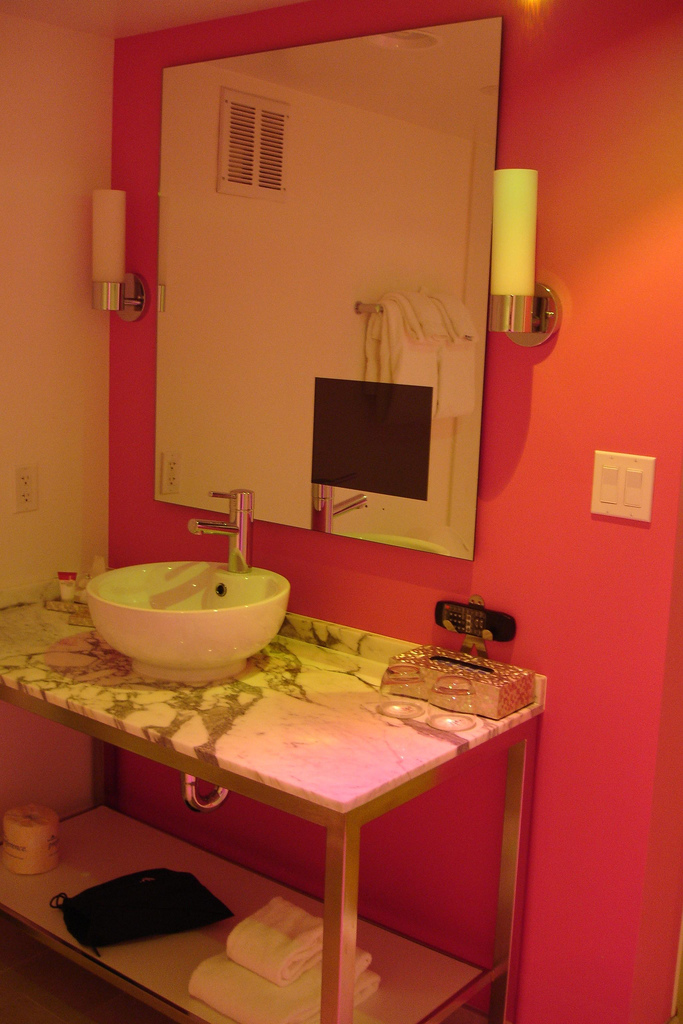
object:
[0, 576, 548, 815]
countertop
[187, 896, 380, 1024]
stack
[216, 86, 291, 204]
air vent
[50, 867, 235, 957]
bag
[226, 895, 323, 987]
towel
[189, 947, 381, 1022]
towel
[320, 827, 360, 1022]
leg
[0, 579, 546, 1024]
counter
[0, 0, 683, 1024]
bathroom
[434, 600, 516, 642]
remote control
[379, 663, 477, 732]
glasses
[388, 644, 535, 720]
flower design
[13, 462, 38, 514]
outlet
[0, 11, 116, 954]
wall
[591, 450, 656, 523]
light switch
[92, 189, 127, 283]
globe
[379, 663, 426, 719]
glass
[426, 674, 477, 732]
glass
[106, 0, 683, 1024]
wall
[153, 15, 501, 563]
mirror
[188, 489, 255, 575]
faucet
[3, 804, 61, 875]
roll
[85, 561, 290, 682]
bowl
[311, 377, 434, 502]
mirror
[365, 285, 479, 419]
hand towels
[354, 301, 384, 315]
rail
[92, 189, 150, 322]
fixture